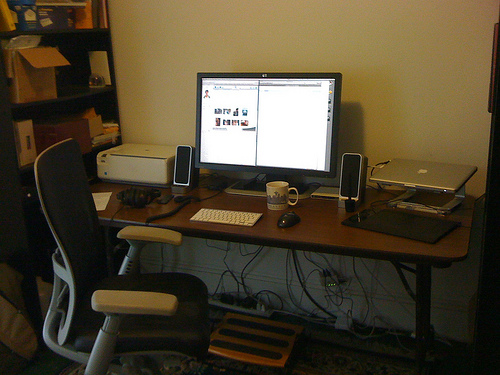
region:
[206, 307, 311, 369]
A wood foot rest on the floor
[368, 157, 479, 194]
A silver lap top computer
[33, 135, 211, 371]
A black and gray office chair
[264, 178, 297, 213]
A coffee mug on the desk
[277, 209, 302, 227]
A black computer mouse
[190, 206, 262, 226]
A small white computer keyboard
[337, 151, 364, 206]
A silver and black speaker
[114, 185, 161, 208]
Headphones lying on the desk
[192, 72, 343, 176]
A large computer monitor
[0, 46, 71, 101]
A cardboard box on the shelf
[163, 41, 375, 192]
this is a computer monitor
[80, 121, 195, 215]
this is a printer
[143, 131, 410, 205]
this is a set of speakers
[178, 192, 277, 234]
this is a keyboard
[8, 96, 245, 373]
this is a chair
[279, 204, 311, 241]
this is a mouse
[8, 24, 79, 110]
brown box on shelf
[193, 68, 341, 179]
computer screen turned on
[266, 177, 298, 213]
coffee mug on the table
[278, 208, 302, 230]
black mouse on table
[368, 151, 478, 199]
laptop sitting on stand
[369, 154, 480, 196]
the laptop is gray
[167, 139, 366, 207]
black and gray speakers on desk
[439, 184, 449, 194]
light on the laptop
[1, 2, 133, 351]
shelf beside the desk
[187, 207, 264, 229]
the keyboard is white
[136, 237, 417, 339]
cords behind the desk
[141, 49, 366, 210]
monitor on the table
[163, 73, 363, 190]
monitor that is turned on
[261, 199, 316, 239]
mouse on the table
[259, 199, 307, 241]
black mouse on table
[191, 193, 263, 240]
keyboard on the table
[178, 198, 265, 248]
white keyboard in photo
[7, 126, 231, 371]
chair next to the table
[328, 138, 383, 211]
speaker next to monitor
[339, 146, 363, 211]
computer speaker on the right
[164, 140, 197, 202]
computer speaker on the left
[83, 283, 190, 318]
the right side arm rest on the chair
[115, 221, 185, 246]
the left side arm rest on the chair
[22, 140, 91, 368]
the back of the computer chair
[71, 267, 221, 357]
the seat of the computer chair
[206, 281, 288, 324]
several things plugged into the surge protector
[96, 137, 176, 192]
a printer on the computer desk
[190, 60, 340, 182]
the flat screen monitor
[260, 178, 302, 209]
a white and blue coffee mug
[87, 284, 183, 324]
Armrest of a chair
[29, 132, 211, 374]
a black and grey office chair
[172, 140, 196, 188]
a computer speaker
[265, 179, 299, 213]
a coffee cup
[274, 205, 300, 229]
a black computer mouse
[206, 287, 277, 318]
an overloaded power strip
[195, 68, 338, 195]
a computer monitor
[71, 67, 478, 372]
a desk with electronics on it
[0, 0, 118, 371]
a crowded shelf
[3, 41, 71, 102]
an open box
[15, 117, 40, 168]
a book on a shelf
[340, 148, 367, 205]
a tall black and gray speaker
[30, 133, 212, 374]
a black and gray computer chair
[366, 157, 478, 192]
a gray laptop computer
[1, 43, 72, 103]
a brown box